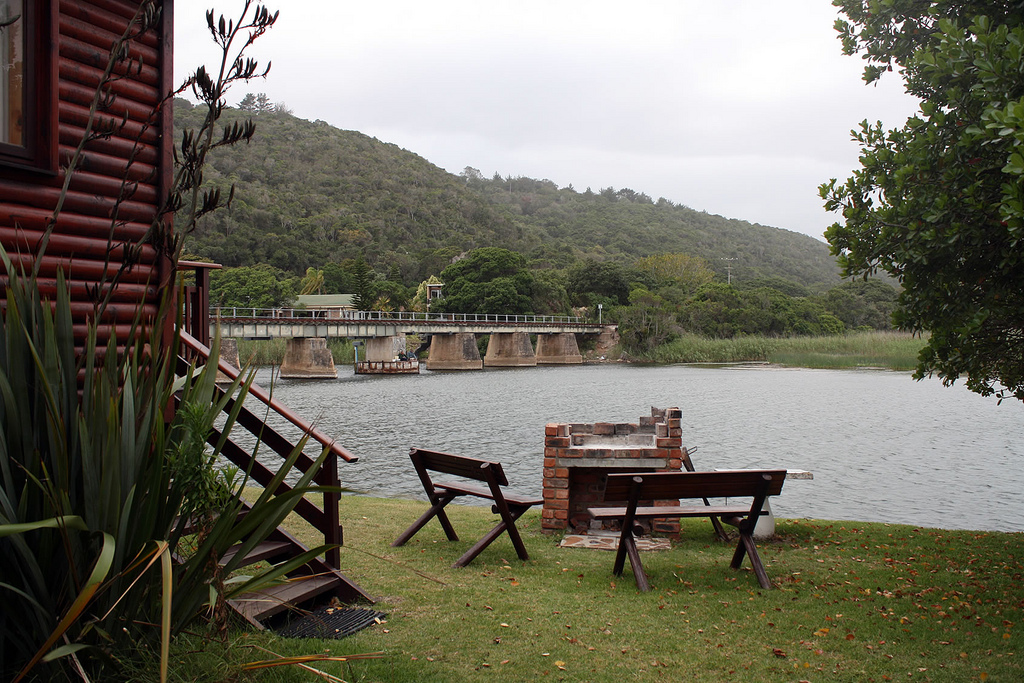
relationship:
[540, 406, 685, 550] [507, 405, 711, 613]
brick has brick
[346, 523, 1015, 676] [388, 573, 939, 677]
leaves on ground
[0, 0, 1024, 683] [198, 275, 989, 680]
outdoors takes place outdoors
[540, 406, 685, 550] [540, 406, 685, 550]
brick made of brick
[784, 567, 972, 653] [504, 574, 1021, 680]
leaves on ground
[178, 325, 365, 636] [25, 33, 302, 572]
stairs by building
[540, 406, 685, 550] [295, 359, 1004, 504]
brick by lake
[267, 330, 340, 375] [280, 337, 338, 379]
bridges has bridges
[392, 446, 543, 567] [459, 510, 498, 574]
bench has legs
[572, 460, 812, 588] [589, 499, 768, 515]
bench has seat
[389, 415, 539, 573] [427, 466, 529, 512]
bench has seat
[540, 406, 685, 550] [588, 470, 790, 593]
brick with bench